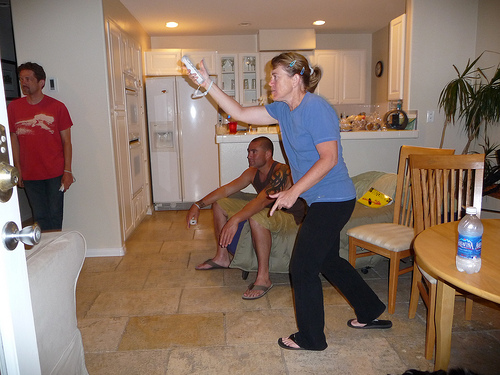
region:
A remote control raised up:
[186, 60, 192, 67]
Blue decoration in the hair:
[291, 62, 293, 65]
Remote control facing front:
[191, 221, 195, 223]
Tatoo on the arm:
[275, 178, 281, 185]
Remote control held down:
[60, 187, 62, 191]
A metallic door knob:
[26, 231, 33, 240]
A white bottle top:
[469, 208, 473, 213]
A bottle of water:
[461, 261, 476, 269]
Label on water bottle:
[459, 248, 478, 253]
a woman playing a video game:
[178, 50, 390, 348]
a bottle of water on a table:
[456, 205, 485, 272]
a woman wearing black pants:
[289, 200, 384, 342]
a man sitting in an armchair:
[183, 135, 290, 297]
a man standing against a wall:
[6, 60, 73, 231]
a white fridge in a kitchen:
[146, 75, 219, 205]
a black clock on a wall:
[373, 60, 384, 79]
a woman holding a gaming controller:
[179, 50, 212, 97]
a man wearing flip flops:
[193, 258, 275, 297]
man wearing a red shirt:
[8, 95, 75, 179]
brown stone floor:
[118, 265, 258, 345]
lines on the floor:
[136, 255, 236, 338]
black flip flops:
[258, 328, 335, 358]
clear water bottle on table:
[449, 202, 489, 292]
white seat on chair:
[343, 218, 418, 256]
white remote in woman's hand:
[168, 51, 222, 120]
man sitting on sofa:
[184, 138, 294, 253]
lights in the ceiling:
[145, 8, 385, 34]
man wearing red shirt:
[7, 83, 91, 179]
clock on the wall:
[365, 56, 387, 84]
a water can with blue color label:
[455, 205, 486, 275]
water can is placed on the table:
[411, 206, 483, 369]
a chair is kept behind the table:
[406, 148, 491, 368]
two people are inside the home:
[181, 51, 388, 355]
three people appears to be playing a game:
[11, 43, 395, 352]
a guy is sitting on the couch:
[187, 137, 303, 303]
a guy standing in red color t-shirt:
[8, 64, 75, 236]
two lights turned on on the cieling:
[89, 3, 372, 37]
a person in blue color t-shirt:
[181, 55, 391, 352]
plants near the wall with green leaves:
[423, 48, 493, 215]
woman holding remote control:
[172, 47, 229, 115]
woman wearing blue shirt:
[247, 84, 357, 218]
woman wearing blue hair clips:
[274, 49, 309, 82]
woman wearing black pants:
[284, 190, 397, 356]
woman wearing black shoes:
[270, 310, 404, 353]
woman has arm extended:
[171, 48, 308, 152]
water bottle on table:
[404, 195, 496, 364]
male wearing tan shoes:
[189, 252, 278, 309]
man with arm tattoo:
[255, 162, 292, 209]